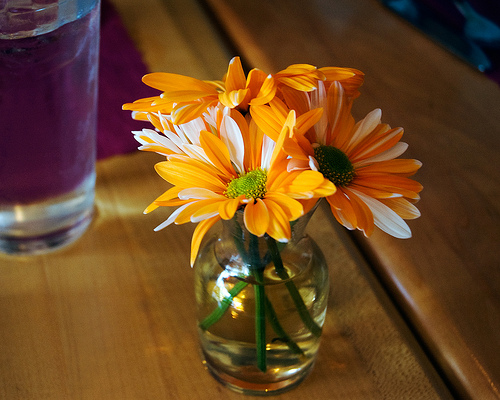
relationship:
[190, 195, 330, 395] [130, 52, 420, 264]
vase holds flowers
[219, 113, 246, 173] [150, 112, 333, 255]
petal on flower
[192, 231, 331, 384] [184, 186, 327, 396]
water in vase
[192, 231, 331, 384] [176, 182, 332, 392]
water in vase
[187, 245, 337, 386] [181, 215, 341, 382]
water in vase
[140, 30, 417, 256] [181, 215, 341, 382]
flowers in vase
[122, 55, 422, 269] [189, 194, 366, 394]
flowers in a vase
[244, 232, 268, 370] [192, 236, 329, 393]
stem in water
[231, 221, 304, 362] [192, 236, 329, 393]
stem in water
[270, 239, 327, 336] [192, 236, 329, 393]
stem in water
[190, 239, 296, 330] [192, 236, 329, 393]
stem in water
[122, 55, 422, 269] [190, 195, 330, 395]
flowers in a vase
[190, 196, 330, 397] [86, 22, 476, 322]
vase on a table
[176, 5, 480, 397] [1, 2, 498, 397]
hole in table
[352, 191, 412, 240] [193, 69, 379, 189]
petal on flower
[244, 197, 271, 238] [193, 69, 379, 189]
petal on flower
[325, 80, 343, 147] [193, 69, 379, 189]
petal on flower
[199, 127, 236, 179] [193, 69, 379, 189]
petal on flower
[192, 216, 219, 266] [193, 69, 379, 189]
petal on flower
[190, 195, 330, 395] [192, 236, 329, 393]
vase has water